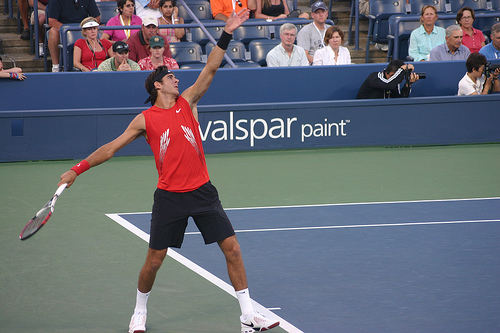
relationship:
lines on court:
[275, 217, 380, 241] [0, 160, 471, 326]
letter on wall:
[198, 111, 348, 145] [7, 96, 481, 156]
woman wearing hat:
[147, 41, 191, 75] [144, 34, 166, 48]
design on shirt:
[158, 125, 204, 176] [142, 93, 208, 189]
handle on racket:
[45, 179, 71, 201] [14, 203, 57, 245]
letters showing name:
[196, 109, 353, 152] [197, 111, 348, 146]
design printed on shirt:
[158, 125, 204, 176] [136, 94, 216, 194]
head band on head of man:
[144, 71, 173, 107] [13, 12, 278, 332]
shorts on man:
[144, 179, 244, 250] [56, 7, 280, 333]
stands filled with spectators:
[2, 2, 498, 178] [12, 1, 497, 127]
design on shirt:
[154, 119, 198, 172] [132, 102, 220, 196]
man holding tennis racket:
[71, 50, 281, 330] [18, 170, 72, 242]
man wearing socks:
[56, 7, 280, 333] [234, 284, 252, 319]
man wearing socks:
[56, 7, 280, 333] [128, 281, 153, 320]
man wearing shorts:
[56, 7, 280, 333] [149, 180, 236, 250]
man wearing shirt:
[13, 12, 278, 332] [135, 97, 213, 191]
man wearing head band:
[56, 7, 280, 333] [153, 66, 174, 81]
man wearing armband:
[56, 7, 280, 333] [71, 160, 90, 176]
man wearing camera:
[360, 53, 432, 94] [403, 66, 426, 80]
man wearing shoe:
[56, 7, 280, 333] [235, 307, 287, 329]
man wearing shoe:
[56, 7, 280, 333] [124, 309, 152, 331]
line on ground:
[244, 195, 498, 240] [0, 145, 498, 331]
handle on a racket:
[50, 183, 68, 201] [33, 139, 130, 257]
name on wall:
[195, 108, 353, 148] [212, 111, 371, 175]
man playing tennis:
[56, 7, 280, 333] [96, 108, 203, 233]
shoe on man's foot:
[237, 306, 281, 330] [232, 298, 284, 330]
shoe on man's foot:
[237, 306, 281, 330] [124, 305, 152, 330]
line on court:
[109, 192, 496, 217] [15, 145, 497, 324]